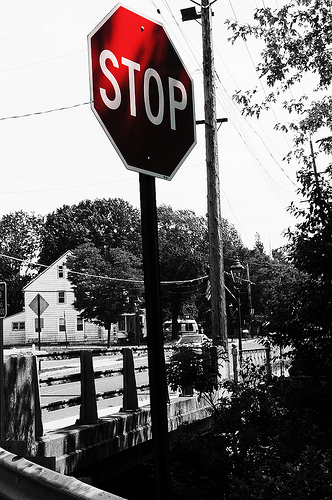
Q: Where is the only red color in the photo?
A: On the stop sign.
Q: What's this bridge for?
A: Vehicle traffic.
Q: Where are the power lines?
A: In the air above the sidewalk.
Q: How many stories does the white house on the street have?
A: Three.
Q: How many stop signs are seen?
A: One.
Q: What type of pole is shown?
A: Utility.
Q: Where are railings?
A: On bridge.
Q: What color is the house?
A: White.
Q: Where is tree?
A: In yard.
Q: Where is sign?
A: On pole.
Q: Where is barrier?
A: With bridge.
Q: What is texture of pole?
A: Rough.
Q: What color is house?
A: White.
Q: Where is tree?
A: Near overpass.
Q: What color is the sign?
A: White and red.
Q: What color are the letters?
A: White.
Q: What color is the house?
A: White.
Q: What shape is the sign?
A: Octagon.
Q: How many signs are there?
A: One.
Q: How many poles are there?
A: Two.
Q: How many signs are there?
A: Two.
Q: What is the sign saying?
A: Stop.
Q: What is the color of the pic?
A: White and black.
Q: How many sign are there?
A: 1.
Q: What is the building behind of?
A: Wood.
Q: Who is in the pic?
A: No one.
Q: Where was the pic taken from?
A: The street.